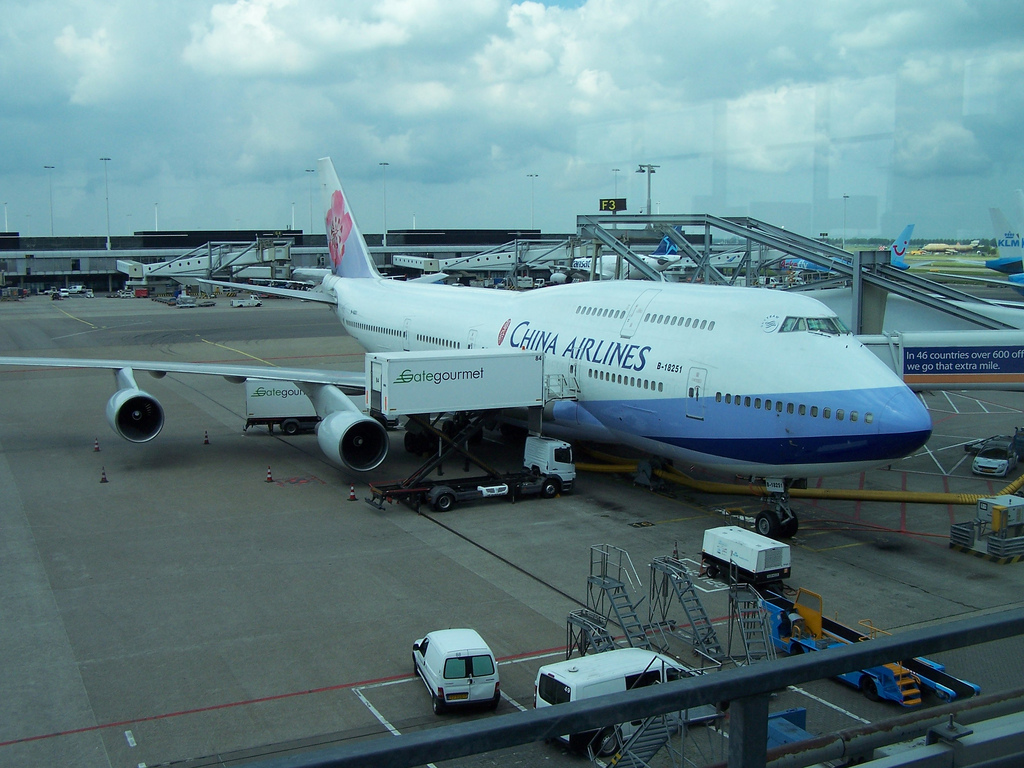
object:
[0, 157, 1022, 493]
airplane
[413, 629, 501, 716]
van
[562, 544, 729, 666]
stairs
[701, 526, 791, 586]
luggage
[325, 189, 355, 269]
pink logo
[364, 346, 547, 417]
white cart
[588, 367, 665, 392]
window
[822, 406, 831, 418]
window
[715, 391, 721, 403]
window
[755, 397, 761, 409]
window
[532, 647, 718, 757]
bus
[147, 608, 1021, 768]
building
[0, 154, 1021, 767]
airport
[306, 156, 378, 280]
tail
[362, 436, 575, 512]
cart